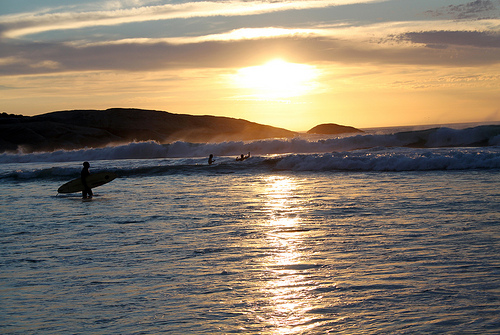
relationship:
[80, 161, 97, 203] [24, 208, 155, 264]
man inside of water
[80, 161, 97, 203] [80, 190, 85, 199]
man has leg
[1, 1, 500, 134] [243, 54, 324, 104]
sky has sun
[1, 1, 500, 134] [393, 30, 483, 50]
sky has cloud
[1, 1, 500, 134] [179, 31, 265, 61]
sky has cloud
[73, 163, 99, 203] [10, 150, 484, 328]
man in ocean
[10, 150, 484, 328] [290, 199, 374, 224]
ocean has wave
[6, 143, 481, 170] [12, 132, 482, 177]
wave approaching shore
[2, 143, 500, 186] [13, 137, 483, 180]
wave near shore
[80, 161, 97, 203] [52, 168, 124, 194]
man has board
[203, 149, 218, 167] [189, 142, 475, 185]
person in wave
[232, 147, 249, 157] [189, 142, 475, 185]
person in wave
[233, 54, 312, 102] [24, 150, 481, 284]
sun shines on water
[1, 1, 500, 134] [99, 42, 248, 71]
sky has cloud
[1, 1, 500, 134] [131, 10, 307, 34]
sky has cloud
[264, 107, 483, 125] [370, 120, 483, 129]
horizon has water line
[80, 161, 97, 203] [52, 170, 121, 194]
man carries board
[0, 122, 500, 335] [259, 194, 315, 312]
ocean has sun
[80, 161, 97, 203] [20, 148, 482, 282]
man standing in ocean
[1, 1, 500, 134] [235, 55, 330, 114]
sky has sun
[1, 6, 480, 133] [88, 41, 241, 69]
sky has cloud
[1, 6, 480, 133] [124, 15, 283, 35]
sky has cloud